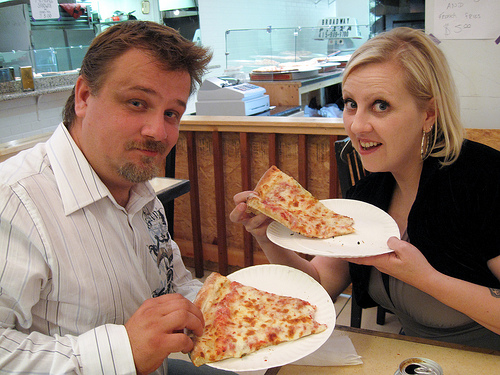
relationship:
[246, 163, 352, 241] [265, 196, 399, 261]
pizza slice on plate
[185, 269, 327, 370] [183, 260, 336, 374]
pizza slice on plate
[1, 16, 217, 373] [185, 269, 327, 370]
man eating pizza slice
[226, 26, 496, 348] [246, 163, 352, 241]
woman eating pizza slice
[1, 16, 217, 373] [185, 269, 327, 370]
man enjoying a pizza slice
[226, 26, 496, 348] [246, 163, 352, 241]
woman enjoying a pizza slice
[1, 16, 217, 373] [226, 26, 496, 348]
man beside of woman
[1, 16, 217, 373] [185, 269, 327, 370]
man eating a pizza slice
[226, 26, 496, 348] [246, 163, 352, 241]
woman eating a pizza slice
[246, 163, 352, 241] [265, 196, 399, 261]
pizza slice on a plate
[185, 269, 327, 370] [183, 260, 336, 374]
pizza slice on a plate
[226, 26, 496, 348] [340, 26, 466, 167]
woman has hair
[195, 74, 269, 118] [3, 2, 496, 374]
cash register n room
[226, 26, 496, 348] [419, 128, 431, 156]
woman wearing an earring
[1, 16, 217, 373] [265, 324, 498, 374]
man sitting at table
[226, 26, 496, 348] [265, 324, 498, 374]
woman sitting at a table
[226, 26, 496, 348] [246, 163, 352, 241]
woman holding pizza slice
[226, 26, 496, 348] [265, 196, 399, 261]
woman holding plate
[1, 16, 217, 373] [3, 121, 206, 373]
man wearing a shirt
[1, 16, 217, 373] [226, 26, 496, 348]
man beside woman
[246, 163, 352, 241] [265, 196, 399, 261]
pizza slice sitting on plate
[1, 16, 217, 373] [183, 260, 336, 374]
man holding plate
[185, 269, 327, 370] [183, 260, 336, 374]
pizza slice sitting on plate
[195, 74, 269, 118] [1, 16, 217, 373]
cash register behind man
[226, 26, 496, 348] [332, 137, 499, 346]
woman wearing shirt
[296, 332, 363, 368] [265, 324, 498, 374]
napkin laying on table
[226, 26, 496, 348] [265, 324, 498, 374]
woman sitting at table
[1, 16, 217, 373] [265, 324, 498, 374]
man sitting on table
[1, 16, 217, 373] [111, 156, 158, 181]
man has a goatee